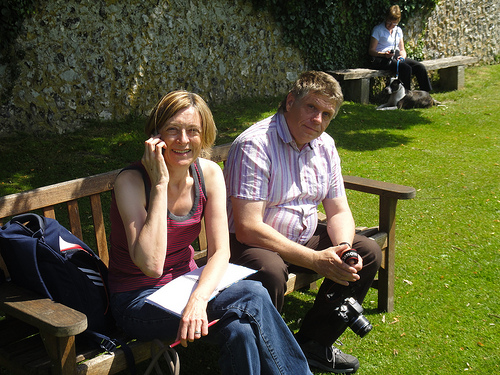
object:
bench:
[0, 141, 417, 374]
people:
[106, 90, 314, 373]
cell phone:
[146, 133, 164, 157]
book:
[144, 257, 257, 322]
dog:
[376, 77, 442, 110]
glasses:
[386, 22, 397, 27]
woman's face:
[383, 16, 401, 30]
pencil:
[169, 317, 219, 348]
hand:
[173, 302, 208, 347]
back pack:
[0, 210, 117, 350]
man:
[223, 70, 382, 373]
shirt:
[223, 113, 349, 249]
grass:
[0, 64, 499, 374]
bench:
[327, 54, 478, 105]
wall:
[1, 1, 499, 139]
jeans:
[109, 279, 314, 374]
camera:
[323, 293, 373, 337]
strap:
[339, 248, 360, 264]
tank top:
[106, 157, 207, 297]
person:
[368, 4, 433, 93]